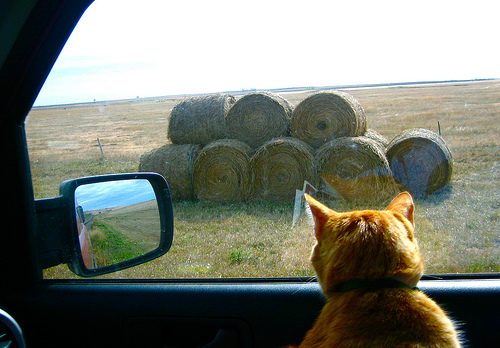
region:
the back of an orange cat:
[299, 190, 470, 347]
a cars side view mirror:
[63, 168, 175, 272]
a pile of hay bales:
[136, 84, 449, 206]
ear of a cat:
[303, 193, 337, 234]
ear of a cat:
[387, 190, 414, 224]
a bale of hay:
[195, 140, 252, 205]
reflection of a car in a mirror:
[72, 200, 97, 270]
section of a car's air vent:
[0, 309, 22, 346]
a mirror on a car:
[73, 180, 162, 268]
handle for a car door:
[125, 318, 250, 345]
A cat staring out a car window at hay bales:
[5, 5, 496, 341]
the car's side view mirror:
[72, 181, 167, 271]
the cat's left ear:
[300, 193, 338, 245]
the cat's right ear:
[381, 188, 420, 225]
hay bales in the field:
[129, 88, 458, 213]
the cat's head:
[296, 187, 437, 294]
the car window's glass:
[23, 45, 496, 273]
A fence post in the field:
[88, 131, 112, 161]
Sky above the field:
[96, 2, 496, 97]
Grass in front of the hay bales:
[175, 207, 491, 269]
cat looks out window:
[265, 191, 462, 344]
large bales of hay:
[149, 87, 454, 172]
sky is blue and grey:
[144, 30, 306, 95]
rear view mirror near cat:
[12, 163, 192, 266]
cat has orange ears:
[290, 195, 417, 252]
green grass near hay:
[233, 202, 290, 269]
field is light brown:
[385, 87, 477, 130]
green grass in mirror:
[90, 212, 128, 255]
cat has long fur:
[320, 296, 452, 346]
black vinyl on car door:
[35, 280, 306, 346]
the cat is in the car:
[267, 160, 497, 332]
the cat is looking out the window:
[284, 190, 469, 340]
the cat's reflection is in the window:
[276, 185, 471, 338]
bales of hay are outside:
[156, 101, 466, 239]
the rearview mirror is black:
[55, 168, 292, 310]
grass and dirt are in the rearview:
[77, 195, 157, 258]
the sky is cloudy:
[80, 55, 164, 149]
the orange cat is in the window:
[295, 200, 473, 287]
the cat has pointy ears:
[294, 187, 481, 207]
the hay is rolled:
[197, 145, 292, 257]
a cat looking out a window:
[298, 190, 468, 345]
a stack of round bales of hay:
[140, 90, 450, 203]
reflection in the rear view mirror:
[75, 177, 162, 272]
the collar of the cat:
[321, 272, 423, 300]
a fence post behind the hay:
[432, 119, 448, 136]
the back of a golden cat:
[294, 193, 466, 347]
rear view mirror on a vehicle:
[37, 170, 176, 280]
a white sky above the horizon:
[37, 2, 498, 107]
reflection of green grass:
[87, 214, 150, 265]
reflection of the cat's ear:
[290, 180, 329, 225]